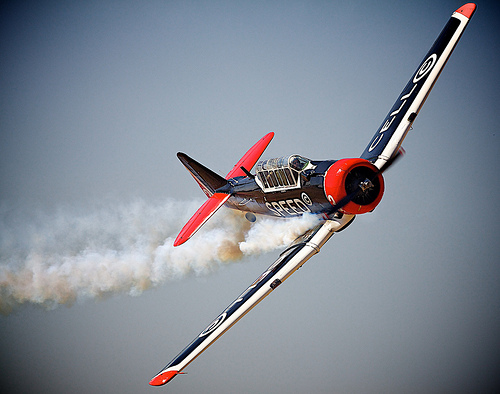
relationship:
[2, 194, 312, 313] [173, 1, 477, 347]
smoke behind plane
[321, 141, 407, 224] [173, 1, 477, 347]
propeller of plane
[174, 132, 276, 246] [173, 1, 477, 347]
tail of plane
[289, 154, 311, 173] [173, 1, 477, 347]
pilot of plane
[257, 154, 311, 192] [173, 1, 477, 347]
windows on top of plane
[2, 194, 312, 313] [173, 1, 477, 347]
smoke from plane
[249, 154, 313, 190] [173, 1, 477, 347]
cockpit of plane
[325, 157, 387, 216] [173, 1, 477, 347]
nose of plane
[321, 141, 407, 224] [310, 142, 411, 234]
propeller has blades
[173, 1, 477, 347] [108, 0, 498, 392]
plane has tricks